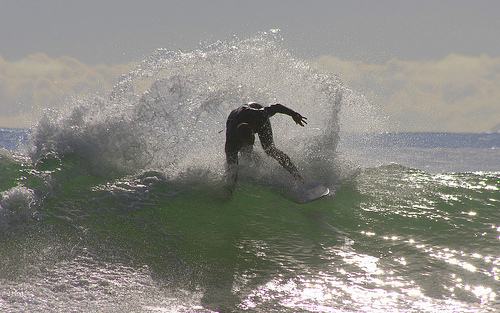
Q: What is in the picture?
A: A surfer.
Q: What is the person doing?
A: Surfing.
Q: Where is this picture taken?
A: The ocean.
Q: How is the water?
A: Big waves.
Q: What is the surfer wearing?
A: A black wetsuit.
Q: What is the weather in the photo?
A: Sunny.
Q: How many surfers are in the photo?
A: One.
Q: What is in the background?
A: Blue sky horizon.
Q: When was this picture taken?
A: Maybe the afternoon.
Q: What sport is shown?
A: Surfing.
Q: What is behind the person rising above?
A: Water.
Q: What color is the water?
A: Blue green.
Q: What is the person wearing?
A: Wetsuit.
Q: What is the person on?
A: Surfboard.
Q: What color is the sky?
A: Blue.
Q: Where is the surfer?
A: Crest of the wave.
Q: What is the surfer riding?
A: Wave.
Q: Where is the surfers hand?
A: Inside the wave.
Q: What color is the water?
A: Green.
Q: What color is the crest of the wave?
A: White.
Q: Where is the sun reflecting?
A: Off of the wave.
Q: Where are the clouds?
A: In the sky.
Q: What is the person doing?
A: Surfing.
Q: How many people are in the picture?
A: 1.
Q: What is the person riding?
A: A wave.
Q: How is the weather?
A: Sunny.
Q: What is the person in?
A: Water.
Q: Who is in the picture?
A: A surfer.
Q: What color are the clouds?
A: White.